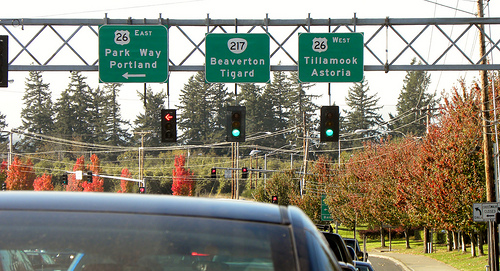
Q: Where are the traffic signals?
A: Below the signs.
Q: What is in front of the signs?
A: Car.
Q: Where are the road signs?
A: Hanging on an overhead rail.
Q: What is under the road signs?
A: Traffic lights.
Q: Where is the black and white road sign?
A: On the telephone pole.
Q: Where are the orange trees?
A: Next to the sidewalk.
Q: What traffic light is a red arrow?
A: The left-most light.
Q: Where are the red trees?
A: Under the left-most traffic light.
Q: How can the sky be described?
A: Grey and cloudy.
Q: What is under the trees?
A: Green grass.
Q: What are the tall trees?
A: Pines.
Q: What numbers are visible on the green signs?
A: 26 and 217.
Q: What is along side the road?
A: Colorful trees.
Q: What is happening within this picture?
A: Traffic moving through a busy street.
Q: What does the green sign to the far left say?
A: Park Way Portland.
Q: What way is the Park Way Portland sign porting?
A: To the left.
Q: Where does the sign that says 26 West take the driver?
A: Tillamook Astoria.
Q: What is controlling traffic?
A: Traffic signals.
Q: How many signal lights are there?
A: 3.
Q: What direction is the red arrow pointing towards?
A: The left.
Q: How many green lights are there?
A: 2.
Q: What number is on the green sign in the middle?
A: 217.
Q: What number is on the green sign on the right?
A: 26.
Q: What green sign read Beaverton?
A: The middle sign.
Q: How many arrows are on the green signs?
A: 1.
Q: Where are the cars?
A: In the street.